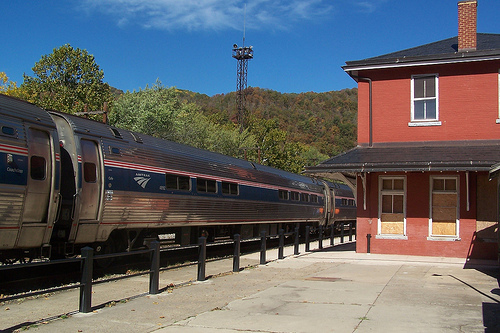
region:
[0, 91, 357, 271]
A shiny train at the station.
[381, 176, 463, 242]
Two partially boarded up windows on the bottom of a red building.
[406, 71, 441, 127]
The top window on a red building.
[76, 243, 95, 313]
First black pole on the bottom left.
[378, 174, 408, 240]
Window on the bottom of the red building closest to the train.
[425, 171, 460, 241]
Window on the red building not closest to the train on the bottom.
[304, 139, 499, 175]
Lower roof on a red building.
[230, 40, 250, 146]
Large tall metal tower beyong the train.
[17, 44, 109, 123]
Tallest tree in the sky.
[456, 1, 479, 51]
Tall brick chimney on a roof.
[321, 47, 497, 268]
Red building with a black roof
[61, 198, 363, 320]
Black fence next to the train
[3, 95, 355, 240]
Silver, blue, red, and white train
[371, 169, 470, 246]
The windows are boarded up with wood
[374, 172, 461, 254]
The windows are white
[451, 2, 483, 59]
The chimney is red brick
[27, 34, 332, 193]
Trees behind the train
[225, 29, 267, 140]
A tall, black tower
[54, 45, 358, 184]
Hillside next to the tracks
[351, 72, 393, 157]
A black storm drain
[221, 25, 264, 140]
tall metal radio tower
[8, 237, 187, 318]
short metal fence in front of the tracks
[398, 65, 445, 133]
second story window with white frame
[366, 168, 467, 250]
boarded up windows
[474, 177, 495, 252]
boarded up door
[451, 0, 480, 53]
red brick chimney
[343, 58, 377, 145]
brown rain gutter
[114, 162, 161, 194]
logo on side of train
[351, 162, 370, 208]
white decorative corbel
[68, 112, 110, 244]
train door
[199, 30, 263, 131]
the tower is in the woods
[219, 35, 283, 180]
the tower is in the woods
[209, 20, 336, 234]
the tower is in the woods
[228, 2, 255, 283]
tall metal radio tower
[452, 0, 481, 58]
brick chimney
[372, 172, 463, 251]
windows boarded up with plywood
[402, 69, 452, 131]
window with white framing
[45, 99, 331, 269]
shiny silver commuter train car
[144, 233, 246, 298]
short fence posts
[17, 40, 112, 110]
top of a tall tree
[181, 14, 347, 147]
mountainside full of foliage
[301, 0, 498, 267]
two story red building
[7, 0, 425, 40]
blue sky with thin white clouds